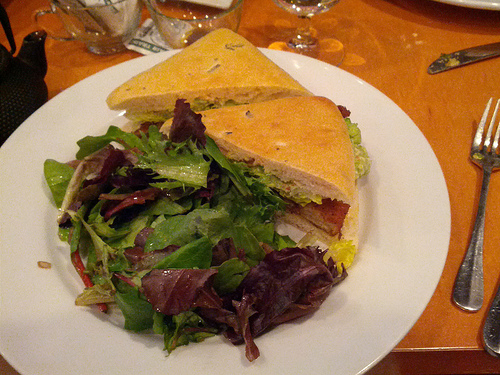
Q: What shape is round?
A: Plate.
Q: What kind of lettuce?
A: Green and purple.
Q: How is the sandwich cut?
A: Half.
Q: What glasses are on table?
A: For drinks.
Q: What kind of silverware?
A: Fork.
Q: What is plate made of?
A: Glass.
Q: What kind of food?
A: Salad.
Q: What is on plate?
A: Sandwich and salad.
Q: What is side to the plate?
A: Fork.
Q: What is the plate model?
A: White.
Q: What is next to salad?
A: Sandwich.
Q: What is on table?
A: Utensils.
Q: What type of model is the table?
A: Wood.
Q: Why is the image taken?
A: Remembrance.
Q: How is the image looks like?
A: Yummy.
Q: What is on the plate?
A: Lettuce and a sandwich.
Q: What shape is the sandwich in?
A: Two triangles.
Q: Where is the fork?
A: To the right of the plate.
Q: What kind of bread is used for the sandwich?
A: Ciabatta.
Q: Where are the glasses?
A: On the table behind the plate.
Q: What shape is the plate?
A: Circular.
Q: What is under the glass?
A: A bill.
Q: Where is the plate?
A: On the table.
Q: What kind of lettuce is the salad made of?
A: Purple and green.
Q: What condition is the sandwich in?
A: Cut into half.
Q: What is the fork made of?
A: Metal.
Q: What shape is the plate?
A: Table.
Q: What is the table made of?
A: Wood.